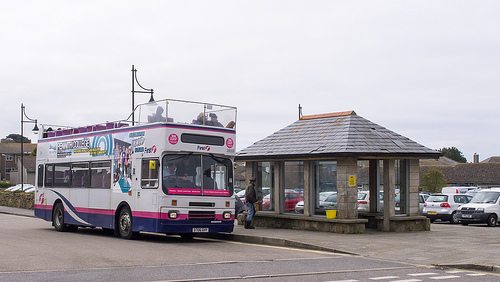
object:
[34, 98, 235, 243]
bus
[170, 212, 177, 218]
headlight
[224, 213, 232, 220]
headlight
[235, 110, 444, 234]
bus stop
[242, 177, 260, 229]
man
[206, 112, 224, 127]
person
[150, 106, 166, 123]
person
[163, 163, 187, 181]
driver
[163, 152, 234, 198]
windshield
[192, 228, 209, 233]
license plate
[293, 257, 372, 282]
pavement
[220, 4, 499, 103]
sky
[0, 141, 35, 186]
building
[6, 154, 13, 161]
windows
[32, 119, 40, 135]
light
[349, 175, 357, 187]
sign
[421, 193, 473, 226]
car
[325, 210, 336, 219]
bucket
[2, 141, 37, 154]
roof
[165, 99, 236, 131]
window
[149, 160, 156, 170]
mirror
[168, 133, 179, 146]
sticker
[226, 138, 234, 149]
sticker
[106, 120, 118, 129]
seats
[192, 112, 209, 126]
people